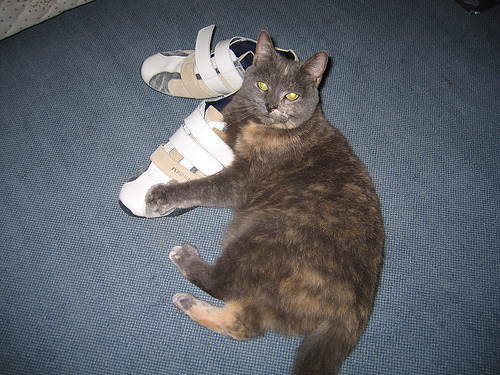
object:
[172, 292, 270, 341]
leg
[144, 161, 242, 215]
leg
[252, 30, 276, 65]
ear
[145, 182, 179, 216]
paw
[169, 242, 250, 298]
legs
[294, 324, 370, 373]
tail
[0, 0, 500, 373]
carpet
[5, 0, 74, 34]
material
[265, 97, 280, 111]
nose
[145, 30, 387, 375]
cat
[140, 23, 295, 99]
sandals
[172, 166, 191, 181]
brand name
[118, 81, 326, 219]
sandals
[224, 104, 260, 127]
whiskers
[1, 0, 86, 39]
fabric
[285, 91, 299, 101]
eye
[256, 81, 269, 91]
eye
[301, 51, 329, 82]
ear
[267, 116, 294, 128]
mouth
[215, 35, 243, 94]
strap